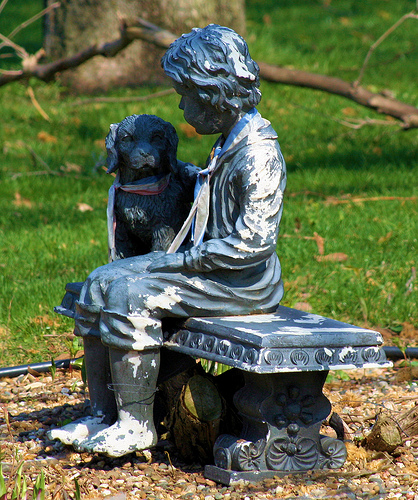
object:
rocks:
[0, 369, 9, 390]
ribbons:
[185, 153, 230, 231]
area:
[249, 7, 415, 99]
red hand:
[80, 397, 158, 463]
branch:
[1, 0, 417, 123]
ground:
[2, 4, 411, 500]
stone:
[32, 385, 39, 395]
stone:
[8, 403, 19, 415]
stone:
[13, 448, 27, 458]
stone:
[42, 470, 56, 474]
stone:
[110, 476, 125, 491]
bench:
[59, 285, 392, 487]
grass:
[1, 1, 416, 369]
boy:
[46, 31, 286, 459]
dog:
[98, 114, 201, 257]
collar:
[118, 173, 179, 195]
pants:
[71, 247, 283, 341]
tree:
[48, 2, 248, 94]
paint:
[81, 421, 164, 457]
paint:
[49, 408, 108, 448]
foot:
[49, 418, 87, 450]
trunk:
[159, 362, 230, 471]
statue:
[45, 23, 395, 489]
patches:
[126, 426, 137, 438]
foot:
[77, 414, 163, 464]